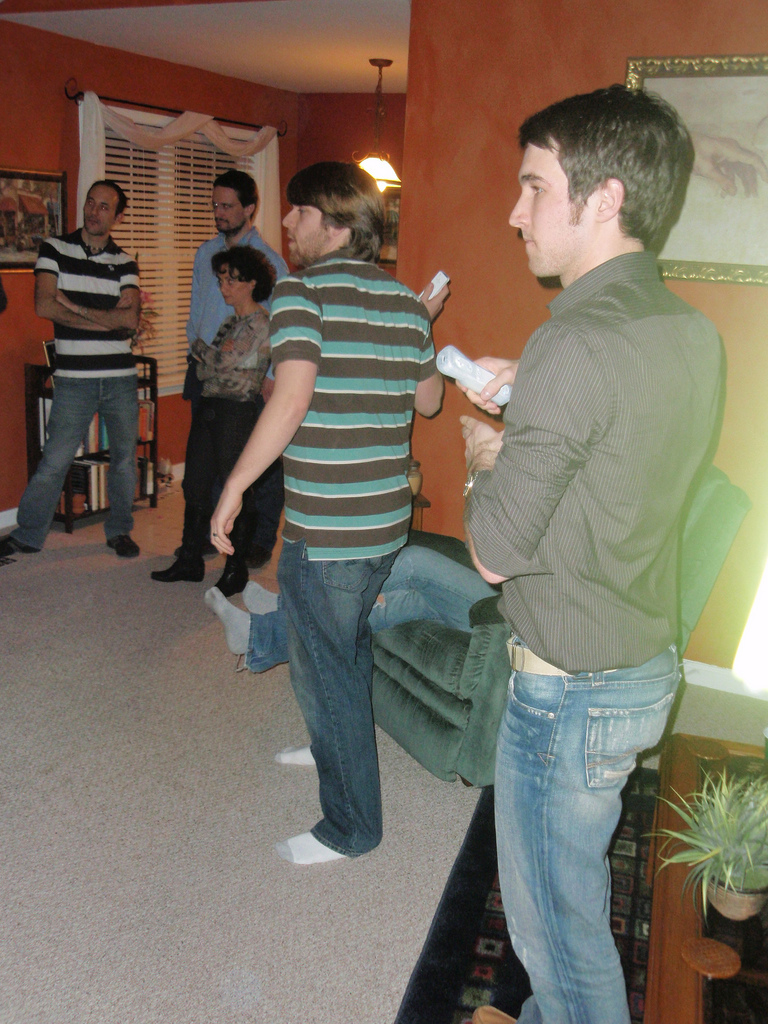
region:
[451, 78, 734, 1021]
man in brown shirt and blue jeans playing wii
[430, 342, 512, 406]
wii remote in hand of man in brown shirt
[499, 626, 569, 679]
khaki colored belt of man in brown shirt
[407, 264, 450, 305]
wii remote in hand of man in blue and brown shirt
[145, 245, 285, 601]
short woman standing in front of man watching boys play a game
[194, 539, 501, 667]
legs of person sitting in green chair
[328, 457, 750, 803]
green chair in living room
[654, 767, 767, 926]
potted plant on table in living room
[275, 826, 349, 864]
sock on foot of man in blue and brown shirt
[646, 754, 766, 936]
small plant on table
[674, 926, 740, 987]
coaster on small table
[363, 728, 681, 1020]
rug under coffee table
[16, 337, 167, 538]
small shelf against wall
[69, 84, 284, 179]
valance above window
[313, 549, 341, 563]
stripe on the shirt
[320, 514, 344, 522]
stripe on the shirt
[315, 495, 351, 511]
stripe on the shirt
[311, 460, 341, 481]
stripe on the shirt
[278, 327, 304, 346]
stripe on the shirt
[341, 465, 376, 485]
stripe on the shirt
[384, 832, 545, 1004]
Rug is in floor.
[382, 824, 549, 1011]
Rug is black color.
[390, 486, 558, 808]
Couch is green color.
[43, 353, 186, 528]
Books are arranged in the rack.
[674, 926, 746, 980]
Drink coaster on coffee table.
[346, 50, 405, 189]
Light hanging from ceiling.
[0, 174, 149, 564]
Man in black and white striped shirt.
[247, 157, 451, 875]
Man in brown and green striped shirt.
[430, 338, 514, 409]
White game controller.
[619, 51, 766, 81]
Gold frame around picture.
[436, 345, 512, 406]
A white game controller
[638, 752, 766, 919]
A potted plant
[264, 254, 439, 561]
A blue and brown striped shirt.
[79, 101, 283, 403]
A window with blinds.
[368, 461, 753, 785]
A small green chair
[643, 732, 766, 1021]
A long wooden table.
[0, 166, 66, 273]
A framed picture on a wall.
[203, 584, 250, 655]
A gray sock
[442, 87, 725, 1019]
a person is standing up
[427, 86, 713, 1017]
a person is playing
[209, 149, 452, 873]
a person is playing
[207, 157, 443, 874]
a person is standing up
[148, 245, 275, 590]
a person is standing up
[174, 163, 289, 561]
a person is standing up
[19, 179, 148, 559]
a person is standing up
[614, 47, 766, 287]
a picture in a frame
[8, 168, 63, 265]
a picture in a frame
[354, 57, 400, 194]
a light hanging from the ceiling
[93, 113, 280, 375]
a window in the room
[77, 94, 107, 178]
white curtains on the window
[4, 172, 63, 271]
a picture on the wall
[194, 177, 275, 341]
a guy in a blue shirt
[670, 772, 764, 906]
a small plant